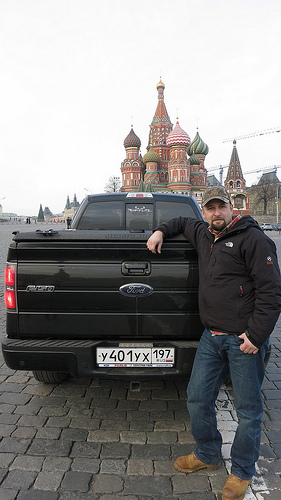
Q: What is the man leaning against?
A: Black truck.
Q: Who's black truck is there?
A: The man leaning on it.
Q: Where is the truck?
A: Behind the man.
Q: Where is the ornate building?
A: Behind the truck.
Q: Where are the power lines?
A: By the castle.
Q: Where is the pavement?
A: Under the truck.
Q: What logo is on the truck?
A: Ford.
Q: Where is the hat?
A: On the man's head.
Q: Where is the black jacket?
A: On the man.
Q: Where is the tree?
A: Right of the castle.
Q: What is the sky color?
A: White.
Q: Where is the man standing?
A: Behind the truck.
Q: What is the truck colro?
A: Black.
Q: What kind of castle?
A: Russian.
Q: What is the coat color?
A: Black.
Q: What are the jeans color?
A: Blue.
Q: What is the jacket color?
A: Black.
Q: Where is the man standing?
A: Behind the truck.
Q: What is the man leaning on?
A: Truck.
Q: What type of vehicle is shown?
A: Truck.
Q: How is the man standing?
A: He's leaning on his truck.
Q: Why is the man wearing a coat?
A: Because it's chilly out.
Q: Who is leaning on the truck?
A: The man.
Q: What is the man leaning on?
A: The truck.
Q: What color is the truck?
A: Black.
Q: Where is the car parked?
A: Outside of the building.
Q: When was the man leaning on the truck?
A: While it was parked outside of the building.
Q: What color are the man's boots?
A: Beige.